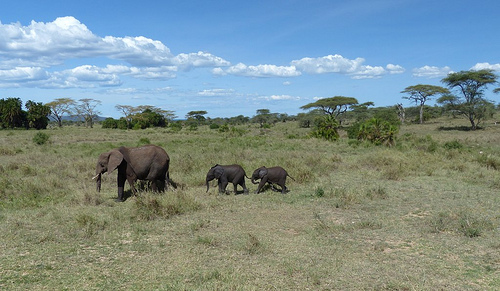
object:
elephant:
[204, 164, 241, 205]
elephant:
[93, 144, 179, 204]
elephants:
[93, 131, 289, 211]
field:
[0, 141, 500, 272]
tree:
[109, 102, 170, 137]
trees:
[0, 65, 500, 146]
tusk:
[94, 170, 101, 181]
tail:
[162, 160, 171, 188]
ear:
[101, 135, 130, 172]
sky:
[0, 5, 500, 116]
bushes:
[315, 103, 421, 161]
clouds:
[21, 21, 144, 86]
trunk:
[93, 169, 103, 194]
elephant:
[253, 166, 290, 191]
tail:
[243, 163, 249, 184]